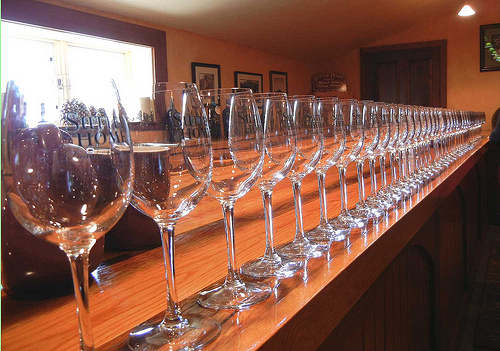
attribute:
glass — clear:
[123, 82, 212, 351]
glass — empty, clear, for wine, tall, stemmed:
[192, 83, 272, 313]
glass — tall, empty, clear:
[252, 88, 307, 294]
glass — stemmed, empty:
[312, 95, 352, 258]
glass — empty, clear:
[338, 94, 368, 238]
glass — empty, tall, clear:
[122, 85, 225, 318]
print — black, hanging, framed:
[191, 63, 224, 110]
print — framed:
[231, 69, 262, 102]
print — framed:
[269, 68, 288, 100]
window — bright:
[3, 19, 156, 124]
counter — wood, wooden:
[13, 111, 484, 349]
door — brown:
[357, 44, 446, 114]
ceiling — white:
[69, 0, 456, 66]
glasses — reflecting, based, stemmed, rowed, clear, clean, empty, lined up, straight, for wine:
[6, 58, 486, 350]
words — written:
[64, 106, 132, 148]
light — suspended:
[454, 1, 478, 18]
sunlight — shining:
[0, 21, 166, 127]